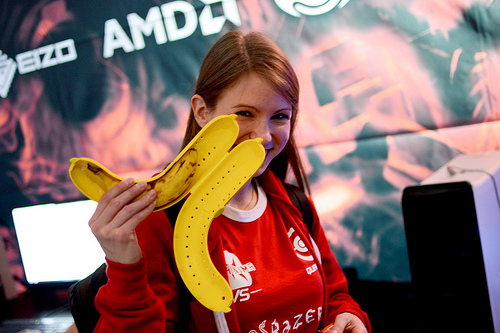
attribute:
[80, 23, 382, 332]
woman — standing up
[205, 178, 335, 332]
shirt — red 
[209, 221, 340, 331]
logos — white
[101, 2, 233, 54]
writing — white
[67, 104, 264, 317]
banana holder — plastic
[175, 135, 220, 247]
holes — small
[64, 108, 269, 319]
holder — plastic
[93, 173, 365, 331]
jacket — red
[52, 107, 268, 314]
banana holder — yellow 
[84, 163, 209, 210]
banana — yellow 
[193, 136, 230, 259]
holder — banana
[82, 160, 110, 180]
stem — yellow